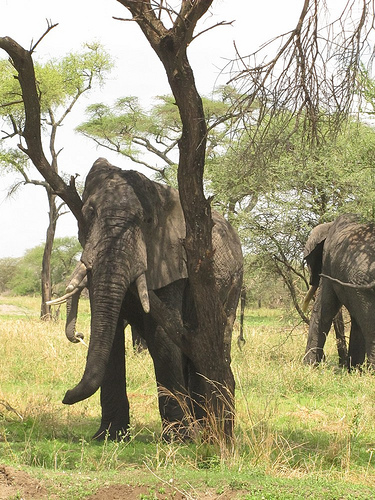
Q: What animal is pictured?
A: Elephant.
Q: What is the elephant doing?
A: Rubbing on tree.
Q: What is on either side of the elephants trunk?
A: Tusks.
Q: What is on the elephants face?
A: Trunk.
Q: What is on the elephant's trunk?
A: Wrinkles.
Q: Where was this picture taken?
A: Wild.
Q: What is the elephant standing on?
A: Grass.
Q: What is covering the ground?
A: Grass.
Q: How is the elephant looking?
A: Gray.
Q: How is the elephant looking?
A: Gray.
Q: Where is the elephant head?
A: Tree branch.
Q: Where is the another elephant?
A: Away.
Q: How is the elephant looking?
A: Large.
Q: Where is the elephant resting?
A: Tree.